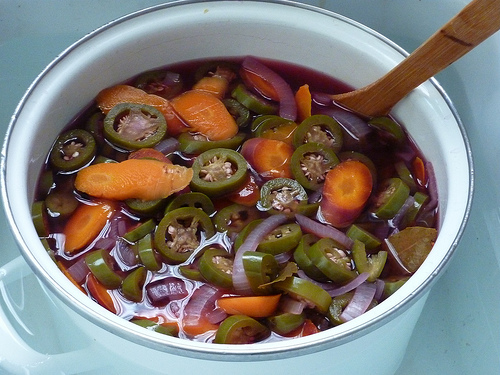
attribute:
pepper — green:
[191, 144, 251, 197]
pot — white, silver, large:
[10, 9, 481, 361]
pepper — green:
[100, 90, 168, 150]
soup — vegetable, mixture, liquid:
[74, 68, 395, 301]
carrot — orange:
[62, 202, 117, 253]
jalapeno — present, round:
[287, 103, 344, 182]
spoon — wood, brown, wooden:
[324, 8, 497, 118]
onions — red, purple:
[297, 203, 355, 254]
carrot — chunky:
[318, 162, 378, 229]